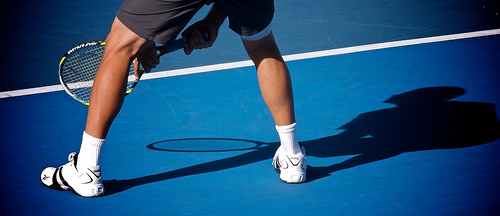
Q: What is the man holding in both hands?
A: Tennis racket.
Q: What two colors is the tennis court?
A: Blue and white.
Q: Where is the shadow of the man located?
A: On tennis court.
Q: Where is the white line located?
A: On tennis court.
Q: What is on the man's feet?
A: White socks and sneakers.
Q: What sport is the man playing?
A: Tennis.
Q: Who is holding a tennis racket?
A: A man.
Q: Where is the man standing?
A: On tennis court.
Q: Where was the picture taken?
A: On a tennis court.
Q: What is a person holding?
A: Tennis racket.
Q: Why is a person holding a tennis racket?
A: To hit the ball.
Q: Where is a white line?
A: On the court.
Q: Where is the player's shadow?
A: On the court.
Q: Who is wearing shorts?
A: The player.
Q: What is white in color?
A: Player's socks.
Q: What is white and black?
A: Sneakers.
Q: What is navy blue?
A: Player's shorts.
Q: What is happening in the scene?
A: A tennis game.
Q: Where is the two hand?
A: On a racket.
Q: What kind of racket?
A: Tennis racket.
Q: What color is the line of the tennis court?
A: White.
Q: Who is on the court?
A: Tennis player.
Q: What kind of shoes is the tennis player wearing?
A: Tennis shoe.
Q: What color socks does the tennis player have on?
A: White.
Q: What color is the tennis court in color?
A: Blue.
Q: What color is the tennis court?
A: Blue.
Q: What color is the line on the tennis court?
A: White.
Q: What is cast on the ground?
A: Shadows.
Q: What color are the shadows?
A: Black.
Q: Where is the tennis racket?
A: In the person's hand.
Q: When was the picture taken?
A: Daytime.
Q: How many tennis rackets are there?
A: One.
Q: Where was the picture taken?
A: A tennis court.